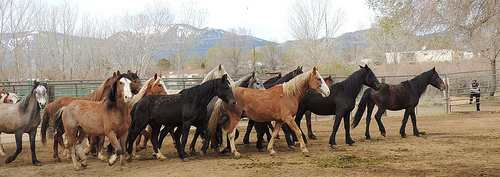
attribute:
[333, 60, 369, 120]
horse — black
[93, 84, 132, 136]
horse — brown, galloping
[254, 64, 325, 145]
horse — brown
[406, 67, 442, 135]
horse — black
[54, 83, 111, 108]
horse — brown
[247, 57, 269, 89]
horse — white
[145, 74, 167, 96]
horse — brown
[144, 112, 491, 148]
ground — dry, tan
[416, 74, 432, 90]
mane — black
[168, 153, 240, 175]
ground — dirt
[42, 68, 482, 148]
horses — walking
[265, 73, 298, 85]
horse — black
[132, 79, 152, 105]
mane — white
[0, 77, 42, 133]
horse — grey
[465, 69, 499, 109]
person — standing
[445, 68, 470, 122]
fence — metal, split-rail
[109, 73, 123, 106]
mane — black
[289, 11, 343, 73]
trees — bare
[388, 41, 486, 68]
building — white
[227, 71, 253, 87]
mane — grey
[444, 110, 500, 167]
grass — dry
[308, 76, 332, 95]
face — white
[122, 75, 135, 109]
face — white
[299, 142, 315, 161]
hoof — up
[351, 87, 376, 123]
tail — black